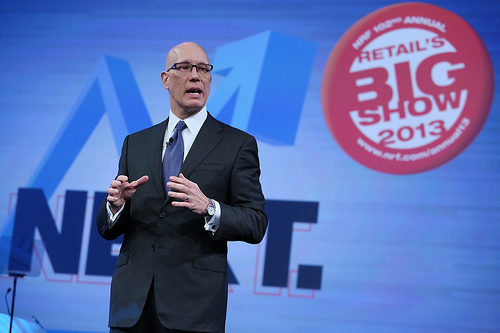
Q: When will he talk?
A: Now.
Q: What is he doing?
A: Talking.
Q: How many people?
A: 1.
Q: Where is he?
A: On stage.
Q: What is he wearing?
A: Suit.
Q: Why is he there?
A: To inform.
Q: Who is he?
A: A man.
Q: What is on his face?
A: Glasses.